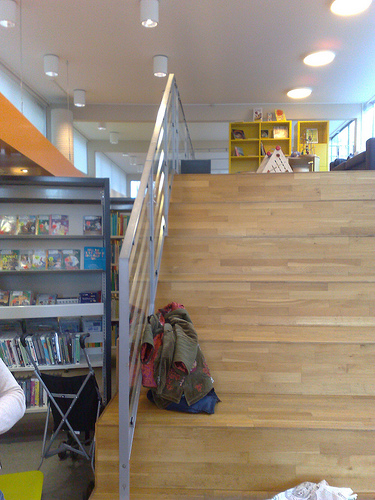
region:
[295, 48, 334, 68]
a light on the ceiling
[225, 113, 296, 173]
a yellow book shelf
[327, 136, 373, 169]
a brown couch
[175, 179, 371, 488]
wooden stairs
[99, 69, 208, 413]
a white balcony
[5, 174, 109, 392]
a large black book shelf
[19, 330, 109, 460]
a black stroller on the ground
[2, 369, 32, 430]
the arm of a person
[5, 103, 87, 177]
an orange wall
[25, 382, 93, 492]
an object in cup board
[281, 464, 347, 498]
a part of the paper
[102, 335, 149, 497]
an iron stand near cup board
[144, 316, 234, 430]
a cloth in floor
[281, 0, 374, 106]
Round lights on the ceiling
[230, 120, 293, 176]
yellow bookcase with several shelves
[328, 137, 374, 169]
brown couch sitting on the second floor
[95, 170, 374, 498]
brown wooden stairs leading to second floor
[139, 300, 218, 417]
pile of coats left on stairs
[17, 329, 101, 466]
baby stroller sitting beside stairs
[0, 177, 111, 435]
bookcase filled with DVDs and books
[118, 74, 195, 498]
silver railing along the steps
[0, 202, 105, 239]
books displayed on a shelf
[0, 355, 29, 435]
arm of patron using the library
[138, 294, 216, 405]
this is a coat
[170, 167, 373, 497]
this is a stair way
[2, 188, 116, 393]
this is a book shelve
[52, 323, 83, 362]
these are books on the shelve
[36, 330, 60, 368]
these are books on the shelve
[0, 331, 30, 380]
these are books on the shelve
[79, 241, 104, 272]
these are books on the shelve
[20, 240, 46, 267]
these are books on the shelve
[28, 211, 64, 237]
these are books on the shelve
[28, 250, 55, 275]
these are books on the shelve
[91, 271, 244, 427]
clothes on the stairs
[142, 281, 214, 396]
clothes on brown stairs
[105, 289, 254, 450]
brown stairs with clothes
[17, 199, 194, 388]
books on a shelf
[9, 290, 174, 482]
a stroller in front of a shelf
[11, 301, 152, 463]
a stroller inside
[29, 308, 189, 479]
a toddler stroller in front of shelf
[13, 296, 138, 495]
a toddler stroller inside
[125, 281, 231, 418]
Jacket on the stairs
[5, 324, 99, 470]
Black stroller near the stairs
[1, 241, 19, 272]
book on the shelf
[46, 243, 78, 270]
book on the shelf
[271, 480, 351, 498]
white jacket on the stairs